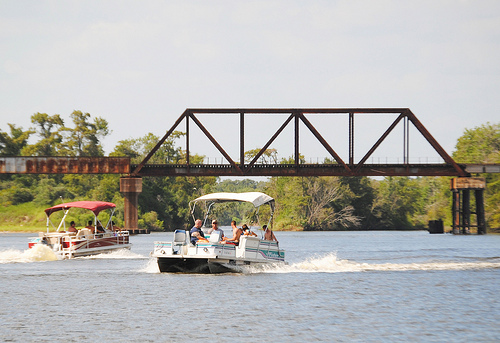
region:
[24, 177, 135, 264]
boat is red with red roof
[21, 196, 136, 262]
Pontoon boat on a river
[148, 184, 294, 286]
Pontoon boat with 5 passengers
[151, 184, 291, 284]
Motoring pontoon boat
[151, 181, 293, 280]
Pontoon boat with grey canopy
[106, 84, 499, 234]
Train trestle bridge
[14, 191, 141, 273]
Moving pontoon boat with red canopy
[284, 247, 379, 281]
Wake from a boat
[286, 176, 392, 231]
Tree on edge of river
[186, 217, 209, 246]
Seated man in blue shirt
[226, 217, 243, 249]
Shirtless man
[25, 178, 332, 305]
Boating summer past time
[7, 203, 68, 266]
Engine creating wake water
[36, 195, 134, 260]
Red boat umbrella shade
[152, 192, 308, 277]
Five men capable boaters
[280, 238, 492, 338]
Water calm except boat wave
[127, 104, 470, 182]
Railroad train bridge water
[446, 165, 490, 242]
Pylon secures railroad bridge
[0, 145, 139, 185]
Bridge continuation lessor type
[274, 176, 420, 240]
Lone island middle water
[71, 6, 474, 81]
Sky muted gray overhead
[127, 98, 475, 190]
railroad bridge with rusty brownish struts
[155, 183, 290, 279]
pontoon boat full of people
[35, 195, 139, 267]
pontoon boat with red sun shade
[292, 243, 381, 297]
white water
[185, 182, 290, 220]
white sunshade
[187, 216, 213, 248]
man in blue shirt seated on pontoon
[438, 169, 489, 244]
rusty pillar of trin bridge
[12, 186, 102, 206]
green foliage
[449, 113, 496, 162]
tree line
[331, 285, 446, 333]
muddy waters of river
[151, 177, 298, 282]
boat is blue and white